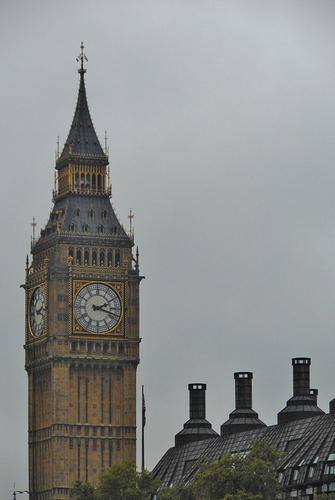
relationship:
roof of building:
[134, 355, 334, 499] [129, 350, 333, 497]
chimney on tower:
[277, 355, 321, 418] [144, 355, 334, 496]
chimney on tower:
[228, 357, 259, 418] [144, 355, 334, 496]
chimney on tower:
[175, 368, 215, 436] [144, 355, 334, 496]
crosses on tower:
[27, 206, 137, 244] [19, 38, 145, 497]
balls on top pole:
[80, 40, 85, 49] [75, 40, 87, 66]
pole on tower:
[75, 40, 87, 66] [19, 38, 145, 497]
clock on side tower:
[71, 280, 123, 335] [2, 39, 169, 496]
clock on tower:
[71, 280, 123, 333] [19, 38, 145, 497]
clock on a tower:
[71, 280, 123, 333] [19, 38, 145, 497]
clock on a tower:
[27, 285, 46, 338] [19, 38, 145, 497]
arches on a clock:
[68, 245, 120, 266] [61, 263, 149, 340]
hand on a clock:
[93, 301, 109, 309] [69, 277, 126, 339]